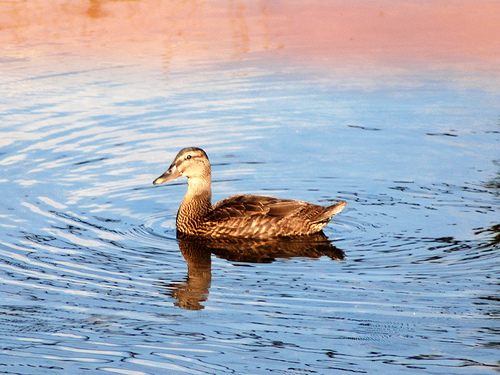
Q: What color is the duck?
A: Brown.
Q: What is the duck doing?
A: Swimming.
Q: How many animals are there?
A: One.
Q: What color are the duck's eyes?
A: Black.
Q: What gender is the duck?
A: Female.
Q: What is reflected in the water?
A: Duck.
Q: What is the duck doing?
A: Swimming.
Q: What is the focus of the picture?
A: Duck.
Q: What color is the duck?
A: Brown.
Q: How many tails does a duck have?
A: One.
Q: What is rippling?
A: Water.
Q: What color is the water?
A: Blue.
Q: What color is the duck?
A: Brown.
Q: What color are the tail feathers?
A: Brown.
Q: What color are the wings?
A: Brown.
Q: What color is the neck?
A: Brown.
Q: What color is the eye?
A: Black.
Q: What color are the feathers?
A: Brown.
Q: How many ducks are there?
A: One.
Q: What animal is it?
A: A duck.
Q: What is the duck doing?
A: Swimming.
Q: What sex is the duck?
A: Female.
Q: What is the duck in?
A: Water.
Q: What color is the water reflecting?
A: Pink.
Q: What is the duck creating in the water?
A: Ripples.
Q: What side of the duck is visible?
A: The left.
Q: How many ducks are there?
A: 1.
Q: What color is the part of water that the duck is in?
A: Water.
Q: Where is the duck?
A: On water.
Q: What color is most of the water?
A: Blue.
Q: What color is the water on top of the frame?
A: Orange.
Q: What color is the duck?
A: Brown.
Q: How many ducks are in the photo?
A: One.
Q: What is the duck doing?
A: Swimming.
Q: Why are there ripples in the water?
A: Movement from duck.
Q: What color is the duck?
A: Brown.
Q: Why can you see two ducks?
A: Reflection.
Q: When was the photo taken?
A: Daytime.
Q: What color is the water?
A: Blue.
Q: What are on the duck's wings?
A: Feathers.